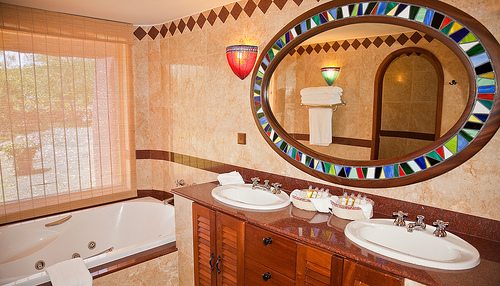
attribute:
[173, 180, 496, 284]
table — brown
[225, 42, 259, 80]
wall light — red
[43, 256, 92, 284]
towel — white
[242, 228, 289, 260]
drawer — brown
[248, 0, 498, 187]
mirror — wall, large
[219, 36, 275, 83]
sconce — red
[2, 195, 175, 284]
bathtub — white, whirlpool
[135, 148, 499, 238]
border — brown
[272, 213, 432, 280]
table — reflective, brown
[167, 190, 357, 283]
cabinets — brown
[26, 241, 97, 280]
towel — white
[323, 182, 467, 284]
sink — white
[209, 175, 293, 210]
sink — white, porcelain, bathroom sink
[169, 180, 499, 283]
vanity — wooden, rich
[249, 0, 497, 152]
pattern — colorful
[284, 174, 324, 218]
basket — small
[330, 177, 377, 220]
basket — small